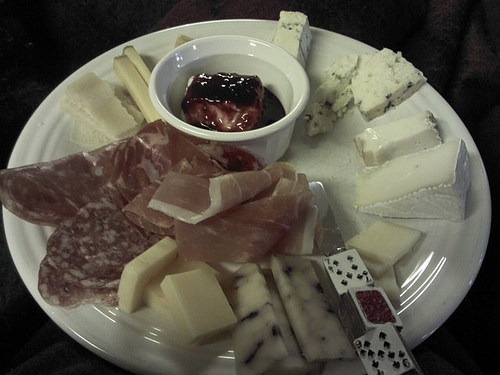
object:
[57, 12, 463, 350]
plater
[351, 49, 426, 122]
cheese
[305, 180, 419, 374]
knife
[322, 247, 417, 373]
handle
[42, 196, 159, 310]
salami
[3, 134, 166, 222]
meats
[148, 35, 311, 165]
bowl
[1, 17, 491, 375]
plate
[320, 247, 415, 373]
designs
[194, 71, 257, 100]
sauce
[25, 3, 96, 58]
tablecloth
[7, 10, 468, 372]
food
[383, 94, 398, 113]
mold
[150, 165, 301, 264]
ham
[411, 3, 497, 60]
cloth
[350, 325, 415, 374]
card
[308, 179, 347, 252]
blade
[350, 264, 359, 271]
spades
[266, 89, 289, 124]
jelly